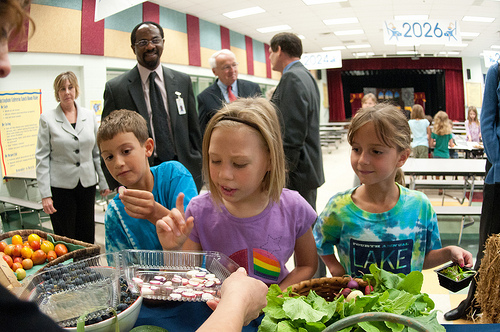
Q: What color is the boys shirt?
A: Blue.